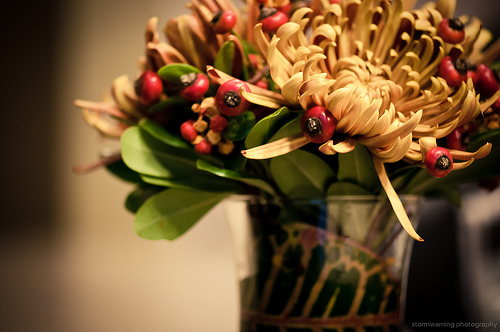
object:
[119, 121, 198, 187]
leaf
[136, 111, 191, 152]
leaf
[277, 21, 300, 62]
petal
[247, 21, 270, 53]
petal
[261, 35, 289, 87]
petal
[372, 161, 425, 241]
petal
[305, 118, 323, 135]
bud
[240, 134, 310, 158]
petal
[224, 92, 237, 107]
end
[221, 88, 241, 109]
bud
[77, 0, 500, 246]
flowers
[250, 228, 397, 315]
detail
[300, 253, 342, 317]
trim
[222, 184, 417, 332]
vase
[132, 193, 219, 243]
leaf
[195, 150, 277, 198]
leaf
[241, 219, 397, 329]
design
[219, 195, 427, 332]
jug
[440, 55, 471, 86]
berry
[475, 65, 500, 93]
berry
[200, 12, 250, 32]
berry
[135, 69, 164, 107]
berry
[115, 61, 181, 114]
part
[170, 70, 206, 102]
part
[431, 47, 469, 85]
part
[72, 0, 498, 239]
plant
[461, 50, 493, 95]
part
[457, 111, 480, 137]
part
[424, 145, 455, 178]
berry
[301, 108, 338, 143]
berry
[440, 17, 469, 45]
berry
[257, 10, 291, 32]
berry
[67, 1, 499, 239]
arrangement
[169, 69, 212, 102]
berry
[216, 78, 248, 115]
berry